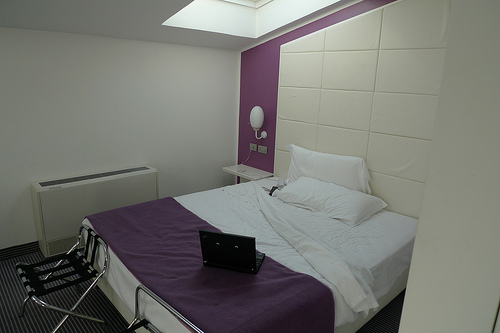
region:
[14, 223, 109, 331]
a metal folding chair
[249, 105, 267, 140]
a white lamp on a purple wall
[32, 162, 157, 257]
an air condition and heating system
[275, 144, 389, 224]
two white bed pillows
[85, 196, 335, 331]
a purple blanket on the foot of the bed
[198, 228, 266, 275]
a black laptop computer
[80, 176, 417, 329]
white linen and a purple blanket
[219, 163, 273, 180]
a small table beside the bed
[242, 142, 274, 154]
two electrical plates on the wall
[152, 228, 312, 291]
a black laptop on top of a purple blanket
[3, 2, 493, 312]
a modern bedroom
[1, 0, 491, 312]
a plush hotel room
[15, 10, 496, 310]
a plush hotel room bed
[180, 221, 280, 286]
an expensive looking laptop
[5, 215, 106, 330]
a fancy luggage holder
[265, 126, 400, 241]
very comfortable fluffy pillows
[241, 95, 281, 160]
modernistic hotel bed lamp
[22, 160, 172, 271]
hotel room heater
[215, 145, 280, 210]
hotel room night stand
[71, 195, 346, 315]
purple hotel bed covers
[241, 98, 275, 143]
small white light fixture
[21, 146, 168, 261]
small room air conditioner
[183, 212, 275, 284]
small black laptop computer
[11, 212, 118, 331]
small metal luggage rack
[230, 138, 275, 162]
small silver wall outlets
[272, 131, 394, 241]
pair of white pillows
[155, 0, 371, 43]
large bright skylight window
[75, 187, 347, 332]
thin purple bed comforter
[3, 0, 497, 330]
small single person room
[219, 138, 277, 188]
small white night stand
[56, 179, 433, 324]
Bed in the middle of the room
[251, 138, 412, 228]
The pillows are white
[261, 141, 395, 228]
There are two pillows on the bed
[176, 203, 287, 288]
The laptop is black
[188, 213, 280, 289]
The laptop is on the bed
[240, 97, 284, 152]
Light with white bulb attached to wall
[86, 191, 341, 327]
Long purple blanket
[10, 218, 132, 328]
Black and silver luggage holder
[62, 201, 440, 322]
The bed is white and purple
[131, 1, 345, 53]
Skylight above the bed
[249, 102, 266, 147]
Lamp on purple wall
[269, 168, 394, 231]
White pillow leaning on white pillow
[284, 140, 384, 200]
White pillow leaning on white wall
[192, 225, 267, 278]
Black laptop is opened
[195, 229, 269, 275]
Black laptop on top of purple blanket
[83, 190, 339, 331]
Purple blanket on bed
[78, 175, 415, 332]
White sheet on bed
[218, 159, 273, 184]
White nightstand table next to bed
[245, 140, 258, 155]
Electrical outlet above table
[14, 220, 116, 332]
Metal chair in front of bed